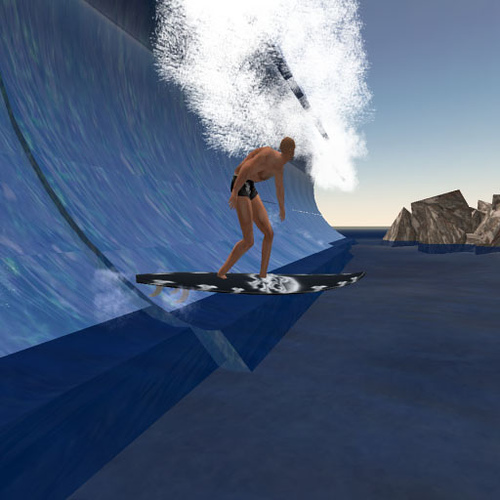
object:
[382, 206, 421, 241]
rocks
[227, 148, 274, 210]
arm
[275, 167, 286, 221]
arm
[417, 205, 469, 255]
large rocks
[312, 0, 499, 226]
background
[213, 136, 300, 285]
man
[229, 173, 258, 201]
swim trunks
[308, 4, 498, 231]
sky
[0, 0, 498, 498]
photo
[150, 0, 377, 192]
wave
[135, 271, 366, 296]
surfboard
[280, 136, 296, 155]
hair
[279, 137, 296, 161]
head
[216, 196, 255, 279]
legs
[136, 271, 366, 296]
color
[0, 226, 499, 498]
water